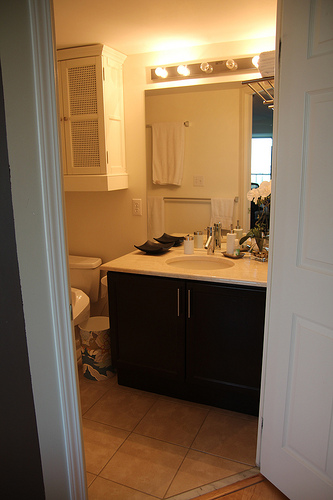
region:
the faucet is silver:
[194, 216, 220, 256]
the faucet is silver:
[195, 220, 222, 268]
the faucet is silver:
[198, 211, 229, 269]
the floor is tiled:
[85, 384, 202, 474]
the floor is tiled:
[85, 380, 231, 491]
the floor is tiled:
[89, 391, 230, 493]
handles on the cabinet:
[172, 286, 201, 327]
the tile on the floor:
[108, 429, 180, 471]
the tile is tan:
[118, 425, 180, 483]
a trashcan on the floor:
[87, 318, 107, 346]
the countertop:
[236, 264, 255, 284]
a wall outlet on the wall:
[132, 197, 144, 219]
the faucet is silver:
[201, 230, 216, 249]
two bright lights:
[151, 66, 196, 79]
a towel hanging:
[205, 199, 233, 221]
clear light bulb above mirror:
[148, 63, 171, 85]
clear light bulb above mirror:
[171, 59, 196, 79]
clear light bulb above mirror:
[199, 56, 215, 76]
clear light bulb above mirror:
[221, 54, 238, 69]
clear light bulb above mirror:
[247, 50, 269, 77]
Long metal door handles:
[185, 284, 192, 336]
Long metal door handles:
[173, 284, 181, 315]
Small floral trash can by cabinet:
[70, 310, 118, 386]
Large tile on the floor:
[199, 413, 255, 471]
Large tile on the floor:
[136, 396, 205, 445]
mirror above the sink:
[140, 88, 277, 242]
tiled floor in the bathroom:
[76, 371, 258, 491]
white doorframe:
[3, 1, 101, 497]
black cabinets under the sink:
[107, 275, 262, 405]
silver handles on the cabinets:
[173, 286, 191, 317]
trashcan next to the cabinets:
[77, 317, 110, 365]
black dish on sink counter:
[138, 237, 164, 258]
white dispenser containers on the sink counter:
[182, 227, 239, 255]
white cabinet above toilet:
[55, 41, 127, 187]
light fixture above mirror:
[143, 54, 265, 79]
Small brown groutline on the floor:
[78, 389, 108, 418]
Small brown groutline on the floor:
[131, 392, 166, 435]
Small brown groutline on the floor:
[185, 405, 221, 457]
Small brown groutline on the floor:
[192, 447, 246, 469]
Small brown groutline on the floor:
[128, 427, 196, 460]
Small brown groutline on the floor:
[83, 413, 124, 439]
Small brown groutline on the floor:
[161, 448, 200, 493]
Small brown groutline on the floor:
[101, 421, 132, 479]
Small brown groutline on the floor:
[98, 467, 150, 496]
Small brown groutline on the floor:
[200, 405, 222, 427]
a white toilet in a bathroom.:
[63, 252, 111, 370]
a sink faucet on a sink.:
[198, 214, 227, 254]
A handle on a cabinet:
[184, 283, 192, 322]